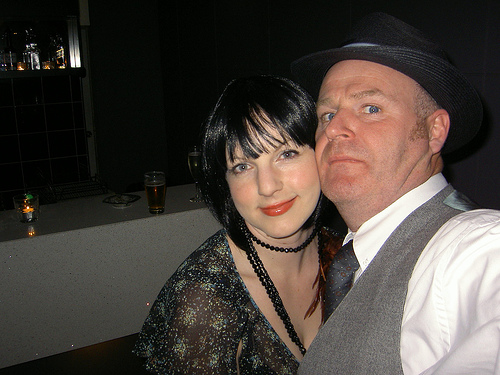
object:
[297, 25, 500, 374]
man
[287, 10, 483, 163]
hat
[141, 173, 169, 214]
glass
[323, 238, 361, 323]
tie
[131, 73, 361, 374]
woman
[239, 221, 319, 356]
necklace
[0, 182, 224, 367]
bar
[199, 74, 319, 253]
hair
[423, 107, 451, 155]
ear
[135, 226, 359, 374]
shirt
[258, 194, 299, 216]
lips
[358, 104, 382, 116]
eye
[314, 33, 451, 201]
head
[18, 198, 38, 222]
candle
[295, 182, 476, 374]
vest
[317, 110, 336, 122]
eye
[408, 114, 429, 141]
sideburn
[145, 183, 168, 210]
beer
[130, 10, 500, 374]
couple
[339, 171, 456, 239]
neck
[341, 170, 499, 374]
shirt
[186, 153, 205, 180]
drink